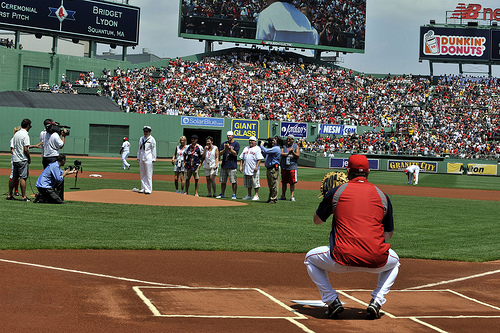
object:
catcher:
[301, 152, 402, 319]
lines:
[1, 258, 500, 333]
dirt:
[0, 246, 497, 333]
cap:
[346, 154, 370, 172]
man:
[5, 118, 33, 202]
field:
[2, 155, 500, 333]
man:
[119, 137, 131, 171]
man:
[238, 135, 264, 201]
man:
[281, 134, 301, 202]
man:
[215, 130, 241, 200]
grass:
[0, 153, 500, 262]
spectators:
[37, 51, 500, 160]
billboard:
[0, 0, 141, 51]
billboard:
[177, 0, 365, 53]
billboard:
[417, 22, 499, 68]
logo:
[423, 29, 486, 57]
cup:
[424, 30, 439, 54]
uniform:
[137, 136, 158, 191]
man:
[137, 125, 157, 194]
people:
[171, 131, 301, 204]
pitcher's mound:
[31, 188, 248, 207]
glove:
[320, 171, 350, 198]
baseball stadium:
[0, 46, 499, 159]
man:
[35, 118, 66, 200]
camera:
[46, 122, 71, 136]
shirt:
[315, 178, 395, 269]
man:
[31, 154, 77, 205]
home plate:
[292, 297, 344, 307]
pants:
[304, 245, 401, 305]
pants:
[121, 152, 129, 168]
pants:
[139, 159, 153, 191]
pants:
[409, 167, 419, 184]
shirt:
[33, 161, 65, 189]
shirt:
[260, 145, 282, 167]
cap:
[249, 136, 257, 141]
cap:
[226, 131, 233, 136]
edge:
[1, 152, 500, 179]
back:
[330, 181, 387, 262]